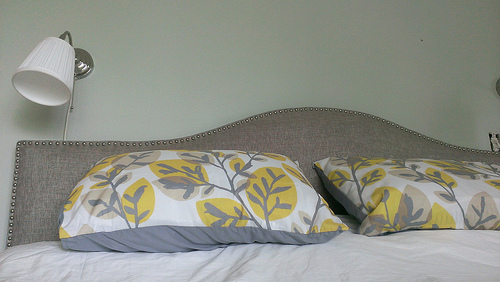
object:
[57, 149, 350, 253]
pillow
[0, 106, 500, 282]
bed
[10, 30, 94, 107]
lamp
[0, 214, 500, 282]
sheet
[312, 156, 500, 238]
pillow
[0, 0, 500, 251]
wall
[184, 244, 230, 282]
lump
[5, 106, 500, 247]
headboard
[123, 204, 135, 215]
leaf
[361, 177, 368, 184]
leaf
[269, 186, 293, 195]
leaf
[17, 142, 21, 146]
nail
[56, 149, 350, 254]
pillowcase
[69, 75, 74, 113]
chain